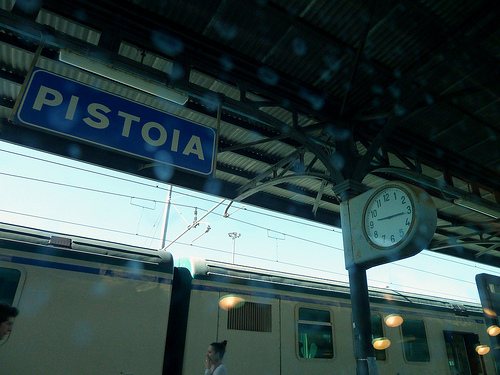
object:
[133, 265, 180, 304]
line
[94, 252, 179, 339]
wall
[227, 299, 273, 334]
vent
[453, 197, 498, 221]
light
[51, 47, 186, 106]
light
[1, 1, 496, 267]
ceiling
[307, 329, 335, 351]
face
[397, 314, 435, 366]
window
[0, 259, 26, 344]
window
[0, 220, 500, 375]
subway train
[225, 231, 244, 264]
light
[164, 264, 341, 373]
sky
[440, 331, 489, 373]
doors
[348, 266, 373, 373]
pole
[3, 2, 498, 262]
roof rafters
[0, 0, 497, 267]
overpass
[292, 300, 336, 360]
window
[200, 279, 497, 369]
reflection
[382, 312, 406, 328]
light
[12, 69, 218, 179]
sign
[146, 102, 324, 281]
window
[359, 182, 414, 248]
clock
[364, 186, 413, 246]
clockface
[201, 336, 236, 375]
woman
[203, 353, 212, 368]
hand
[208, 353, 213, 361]
mouth